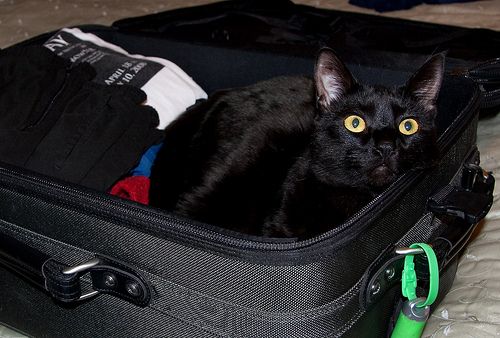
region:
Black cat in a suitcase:
[6, 10, 496, 275]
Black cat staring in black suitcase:
[17, 10, 483, 265]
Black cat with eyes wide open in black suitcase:
[35, 21, 492, 331]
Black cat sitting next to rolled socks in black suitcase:
[105, 20, 480, 331]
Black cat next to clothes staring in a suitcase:
[70, 31, 495, 316]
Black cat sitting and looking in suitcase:
[85, 41, 495, 322]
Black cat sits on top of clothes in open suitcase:
[102, 20, 492, 335]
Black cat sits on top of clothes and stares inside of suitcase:
[96, 25, 492, 290]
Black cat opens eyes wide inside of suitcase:
[110, 7, 495, 327]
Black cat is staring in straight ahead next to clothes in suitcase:
[133, 13, 496, 331]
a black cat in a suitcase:
[6, 4, 487, 336]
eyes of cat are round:
[339, 107, 428, 144]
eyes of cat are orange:
[333, 110, 426, 142]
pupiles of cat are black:
[341, 108, 419, 140]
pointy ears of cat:
[308, 39, 449, 107]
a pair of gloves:
[10, 39, 162, 191]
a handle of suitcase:
[3, 218, 158, 322]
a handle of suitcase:
[367, 150, 497, 336]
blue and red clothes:
[99, 138, 165, 205]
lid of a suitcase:
[100, 0, 499, 115]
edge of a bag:
[212, 288, 246, 335]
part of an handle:
[111, 277, 131, 292]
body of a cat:
[268, 157, 285, 174]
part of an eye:
[340, 123, 355, 128]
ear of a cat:
[323, 79, 330, 89]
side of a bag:
[353, 240, 364, 292]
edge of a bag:
[433, 210, 453, 229]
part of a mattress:
[476, 281, 488, 292]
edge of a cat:
[208, 155, 225, 183]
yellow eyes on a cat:
[345, 107, 421, 140]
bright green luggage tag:
[391, 220, 434, 336]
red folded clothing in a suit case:
[113, 171, 153, 204]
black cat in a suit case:
[147, 29, 450, 266]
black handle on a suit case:
[27, 236, 154, 323]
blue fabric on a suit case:
[135, 131, 160, 182]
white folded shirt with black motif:
[50, 22, 212, 142]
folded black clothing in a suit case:
[16, 55, 135, 190]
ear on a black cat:
[311, 45, 354, 113]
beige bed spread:
[457, 266, 493, 331]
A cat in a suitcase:
[171, 47, 449, 209]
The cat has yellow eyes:
[336, 102, 436, 151]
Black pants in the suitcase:
[8, 94, 158, 151]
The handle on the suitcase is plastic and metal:
[0, 226, 152, 317]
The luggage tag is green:
[388, 234, 440, 334]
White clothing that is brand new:
[35, 21, 225, 110]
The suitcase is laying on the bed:
[353, 197, 498, 337]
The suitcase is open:
[96, 6, 476, 148]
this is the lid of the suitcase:
[103, 4, 490, 99]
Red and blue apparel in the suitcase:
[108, 134, 163, 202]